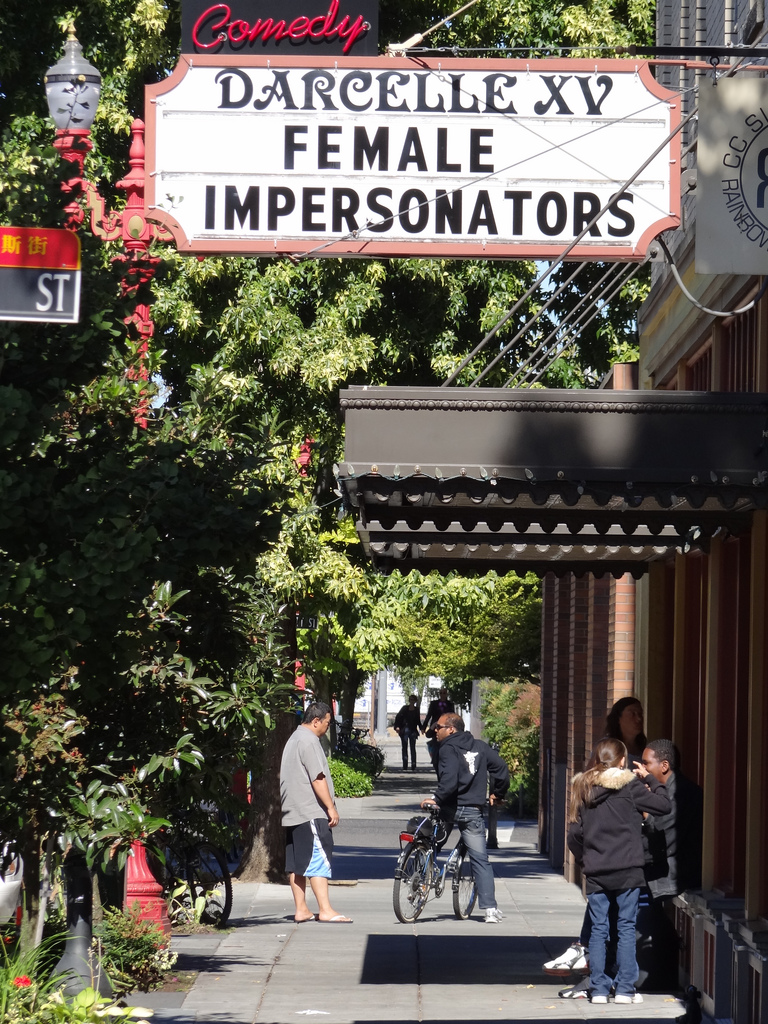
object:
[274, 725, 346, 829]
shirt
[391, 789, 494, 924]
bicycle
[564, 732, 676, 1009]
man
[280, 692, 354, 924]
man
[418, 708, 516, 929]
man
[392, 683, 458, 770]
couple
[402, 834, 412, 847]
reflector light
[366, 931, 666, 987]
shadow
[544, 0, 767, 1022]
building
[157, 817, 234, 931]
bicycle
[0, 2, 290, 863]
tree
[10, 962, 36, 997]
flower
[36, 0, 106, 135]
lamp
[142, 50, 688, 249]
sign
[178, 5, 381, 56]
sign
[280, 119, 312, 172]
letters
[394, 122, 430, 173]
letters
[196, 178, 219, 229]
letters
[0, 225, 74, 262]
sign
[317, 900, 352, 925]
flops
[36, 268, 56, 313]
letters